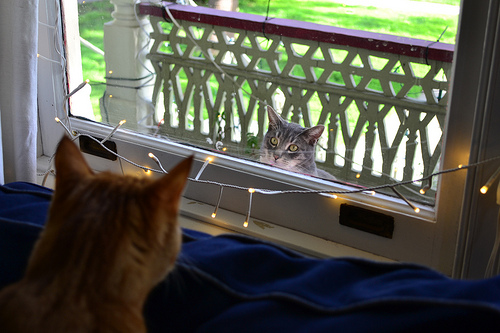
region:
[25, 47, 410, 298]
two cats on opposite sides of window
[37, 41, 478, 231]
string of small white lights across window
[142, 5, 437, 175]
ornate wooden railing on patio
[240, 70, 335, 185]
big yellow eyes on grey striped cat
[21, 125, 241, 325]
orange cat in back on deep-blue blanket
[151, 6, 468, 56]
sun shining on green grass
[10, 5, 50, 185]
white curtain hanging straight down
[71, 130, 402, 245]
dark handles on bottom of window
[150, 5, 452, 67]
dark wood border on top of railing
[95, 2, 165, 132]
carved white pillar at railing end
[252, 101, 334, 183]
cat with yellow eyes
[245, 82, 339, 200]
cat loking in the window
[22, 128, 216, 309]
cat looking out the window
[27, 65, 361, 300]
two cats looking at each other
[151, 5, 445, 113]
ornate wooden fence on the porch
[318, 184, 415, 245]
brass window latch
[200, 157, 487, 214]
white holiday lights strung across the window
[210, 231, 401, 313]
blue blanket on the back of a couch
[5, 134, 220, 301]
orange cat looking at another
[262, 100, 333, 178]
gray cat looking at another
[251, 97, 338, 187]
Cat outside of window.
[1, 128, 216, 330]
Cat inside of house.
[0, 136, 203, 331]
The cat is orange.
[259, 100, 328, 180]
The cat is grey.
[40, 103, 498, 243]
The lights are on.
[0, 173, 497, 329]
The blanket is blue.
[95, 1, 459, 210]
The fence is white.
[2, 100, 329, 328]
Two cats are visible.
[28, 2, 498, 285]
The window frame is white.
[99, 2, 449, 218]
The fence is wooden.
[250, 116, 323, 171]
this is a cat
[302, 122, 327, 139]
this is the ear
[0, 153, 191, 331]
this cat is brown in color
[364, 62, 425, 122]
this is a balcon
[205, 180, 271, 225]
the lights are on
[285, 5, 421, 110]
this is a window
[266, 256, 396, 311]
this is a blanket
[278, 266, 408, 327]
the blanket is blue in color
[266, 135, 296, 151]
the eyes are open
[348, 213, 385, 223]
this is a handle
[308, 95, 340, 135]
part of a mirror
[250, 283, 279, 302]
part of a line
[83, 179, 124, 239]
head of a cat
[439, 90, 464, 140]
edge of a window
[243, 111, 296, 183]
part of a window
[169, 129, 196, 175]
edge of an ear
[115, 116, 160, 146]
part of a window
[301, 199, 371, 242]
part of a board